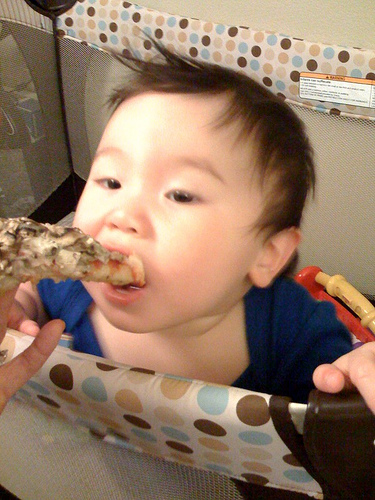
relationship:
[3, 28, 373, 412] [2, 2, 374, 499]
baby in a playpin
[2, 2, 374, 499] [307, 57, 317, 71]
playpin has a dot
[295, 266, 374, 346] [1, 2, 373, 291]
toy in background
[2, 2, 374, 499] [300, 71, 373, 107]
playpin has a warning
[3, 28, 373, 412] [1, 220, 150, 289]
baby eating pizza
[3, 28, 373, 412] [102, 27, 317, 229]
baby has hair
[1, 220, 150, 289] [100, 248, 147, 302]
pizza in mouth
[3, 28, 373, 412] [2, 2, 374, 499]
baby inside playpin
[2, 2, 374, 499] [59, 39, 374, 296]
playpin has a net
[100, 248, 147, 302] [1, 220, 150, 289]
mouth has a pizza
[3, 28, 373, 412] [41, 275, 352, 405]
baby has on a shirt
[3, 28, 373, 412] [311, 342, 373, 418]
baby has a hand